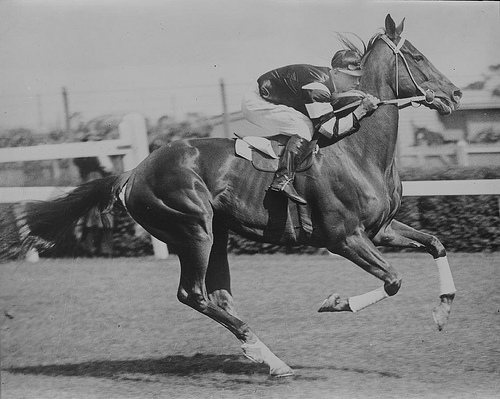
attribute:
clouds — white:
[30, 14, 264, 106]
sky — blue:
[9, 6, 362, 130]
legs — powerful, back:
[139, 194, 294, 379]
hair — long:
[8, 200, 91, 259]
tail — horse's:
[15, 161, 119, 263]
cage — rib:
[221, 163, 288, 236]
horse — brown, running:
[130, 14, 466, 374]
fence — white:
[6, 126, 173, 254]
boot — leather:
[265, 136, 305, 207]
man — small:
[245, 51, 377, 214]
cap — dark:
[333, 43, 363, 73]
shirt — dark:
[258, 63, 362, 135]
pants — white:
[239, 87, 320, 153]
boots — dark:
[269, 140, 315, 205]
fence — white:
[1, 117, 498, 210]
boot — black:
[266, 134, 316, 206]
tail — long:
[8, 169, 123, 255]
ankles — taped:
[339, 282, 389, 317]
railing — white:
[2, 119, 129, 175]